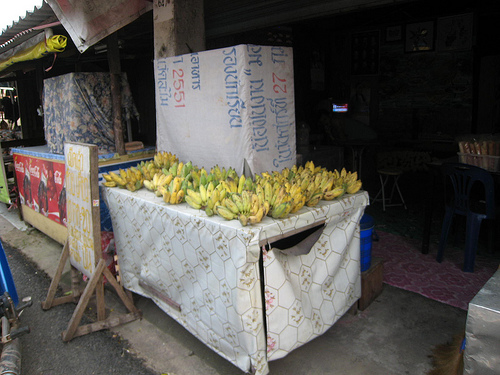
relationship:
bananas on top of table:
[100, 151, 364, 226] [103, 161, 371, 374]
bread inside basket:
[459, 136, 498, 169] [455, 153, 499, 173]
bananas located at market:
[100, 151, 364, 226] [2, 0, 499, 372]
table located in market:
[103, 161, 371, 374] [2, 0, 499, 372]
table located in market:
[10, 141, 159, 251] [2, 0, 499, 372]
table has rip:
[103, 161, 370, 374] [263, 220, 328, 256]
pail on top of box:
[359, 213, 379, 268] [358, 256, 388, 307]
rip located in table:
[263, 220, 328, 256] [103, 161, 370, 374]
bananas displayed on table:
[100, 151, 364, 226] [103, 161, 371, 374]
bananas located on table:
[100, 151, 364, 226] [103, 161, 371, 374]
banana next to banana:
[341, 166, 347, 178] [333, 168, 340, 177]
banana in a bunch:
[249, 204, 264, 224] [217, 189, 270, 225]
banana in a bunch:
[184, 194, 202, 210] [185, 180, 229, 217]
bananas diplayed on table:
[100, 151, 364, 226] [103, 161, 371, 374]